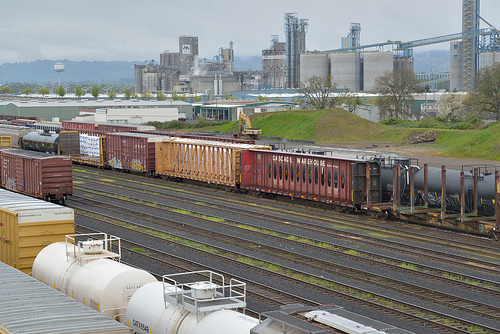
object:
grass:
[260, 110, 313, 140]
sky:
[3, 3, 271, 45]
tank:
[33, 231, 148, 312]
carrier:
[242, 145, 369, 207]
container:
[107, 132, 155, 173]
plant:
[139, 1, 496, 97]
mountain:
[1, 56, 132, 86]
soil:
[395, 142, 443, 155]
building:
[175, 33, 199, 89]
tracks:
[101, 190, 253, 221]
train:
[6, 124, 498, 195]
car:
[156, 137, 239, 187]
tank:
[18, 127, 61, 155]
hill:
[256, 104, 361, 142]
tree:
[156, 92, 167, 102]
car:
[0, 193, 73, 278]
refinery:
[270, 0, 487, 98]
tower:
[49, 62, 66, 98]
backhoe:
[237, 110, 263, 139]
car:
[368, 158, 498, 223]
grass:
[190, 211, 226, 223]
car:
[105, 133, 151, 171]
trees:
[298, 75, 368, 113]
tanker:
[127, 267, 259, 333]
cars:
[104, 135, 152, 170]